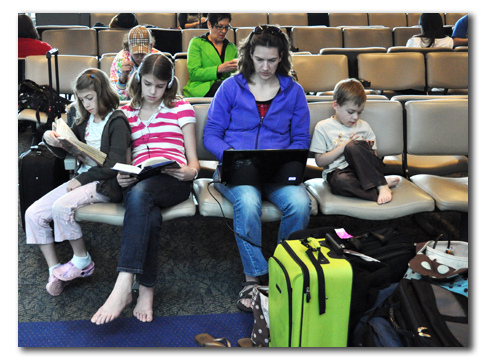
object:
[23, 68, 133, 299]
girl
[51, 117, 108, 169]
book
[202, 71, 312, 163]
jacket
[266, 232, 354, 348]
suitcase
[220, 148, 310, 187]
laptop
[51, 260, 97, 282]
sandals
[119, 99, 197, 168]
shirt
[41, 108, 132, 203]
jacket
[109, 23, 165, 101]
woman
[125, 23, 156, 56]
cap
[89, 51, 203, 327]
girl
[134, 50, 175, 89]
headphones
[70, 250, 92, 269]
socks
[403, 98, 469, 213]
chairs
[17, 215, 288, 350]
carpet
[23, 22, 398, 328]
group of people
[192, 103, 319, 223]
front chairs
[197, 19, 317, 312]
woman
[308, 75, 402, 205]
boy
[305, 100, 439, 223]
chair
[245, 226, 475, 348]
luggage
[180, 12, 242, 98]
woman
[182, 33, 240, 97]
green jacket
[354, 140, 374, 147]
device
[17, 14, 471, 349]
airport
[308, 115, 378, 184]
shirt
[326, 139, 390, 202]
pants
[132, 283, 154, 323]
feet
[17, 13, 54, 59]
woman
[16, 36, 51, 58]
red shirt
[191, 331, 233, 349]
flip flop sandal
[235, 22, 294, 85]
hair